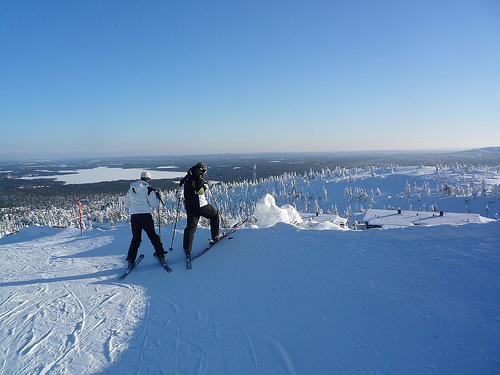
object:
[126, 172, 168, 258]
people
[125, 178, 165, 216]
jacket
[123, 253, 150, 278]
skis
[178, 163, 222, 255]
person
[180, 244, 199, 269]
skis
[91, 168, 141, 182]
water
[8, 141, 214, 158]
distance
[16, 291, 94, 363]
tracks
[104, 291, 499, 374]
snow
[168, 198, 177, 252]
ski poles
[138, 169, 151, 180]
hat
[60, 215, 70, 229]
trees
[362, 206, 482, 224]
roof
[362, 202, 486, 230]
building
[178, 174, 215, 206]
jacket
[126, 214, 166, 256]
pants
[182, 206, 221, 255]
pants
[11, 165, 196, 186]
lake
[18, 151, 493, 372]
mountain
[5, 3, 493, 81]
sky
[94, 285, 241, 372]
shadow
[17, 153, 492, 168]
background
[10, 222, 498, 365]
ground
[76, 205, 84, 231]
safety pole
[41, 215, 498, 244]
cliff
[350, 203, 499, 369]
slope